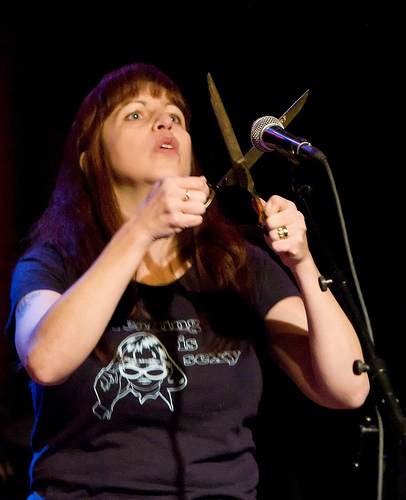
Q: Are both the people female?
A: Yes, all the people are female.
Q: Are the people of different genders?
A: No, all the people are female.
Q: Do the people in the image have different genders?
A: No, all the people are female.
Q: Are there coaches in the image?
A: No, there are no coaches.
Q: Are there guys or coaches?
A: No, there are no coaches or guys.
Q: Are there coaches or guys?
A: No, there are no coaches or guys.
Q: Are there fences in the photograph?
A: No, there are no fences.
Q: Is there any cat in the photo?
A: No, there are no cats.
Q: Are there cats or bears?
A: No, there are no cats or bears.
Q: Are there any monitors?
A: No, there are no monitors.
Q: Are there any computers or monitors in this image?
A: No, there are no monitors or computers.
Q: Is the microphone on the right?
A: Yes, the microphone is on the right of the image.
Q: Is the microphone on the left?
A: No, the microphone is on the right of the image.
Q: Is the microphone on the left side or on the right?
A: The microphone is on the right of the image.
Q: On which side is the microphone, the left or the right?
A: The microphone is on the right of the image.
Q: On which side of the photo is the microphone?
A: The microphone is on the right of the image.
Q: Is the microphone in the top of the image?
A: Yes, the microphone is in the top of the image.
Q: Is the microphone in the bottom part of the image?
A: No, the microphone is in the top of the image.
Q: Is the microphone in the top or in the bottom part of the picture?
A: The microphone is in the top of the image.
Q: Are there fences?
A: No, there are no fences.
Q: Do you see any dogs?
A: No, there are no dogs.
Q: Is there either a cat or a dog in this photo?
A: No, there are no dogs or cats.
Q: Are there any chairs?
A: No, there are no chairs.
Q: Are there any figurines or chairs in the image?
A: No, there are no chairs or figurines.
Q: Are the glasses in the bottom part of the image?
A: Yes, the glasses are in the bottom of the image.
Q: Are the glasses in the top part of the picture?
A: No, the glasses are in the bottom of the image.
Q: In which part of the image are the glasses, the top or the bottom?
A: The glasses are in the bottom of the image.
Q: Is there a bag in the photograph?
A: No, there are no bags.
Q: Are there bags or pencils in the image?
A: No, there are no bags or pencils.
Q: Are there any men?
A: No, there are no men.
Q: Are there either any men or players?
A: No, there are no men or players.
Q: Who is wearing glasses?
A: The girl is wearing glasses.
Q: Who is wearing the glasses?
A: The girl is wearing glasses.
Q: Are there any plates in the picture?
A: No, there are no plates.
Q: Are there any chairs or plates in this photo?
A: No, there are no plates or chairs.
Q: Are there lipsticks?
A: No, there are no lipsticks.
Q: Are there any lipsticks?
A: No, there are no lipsticks.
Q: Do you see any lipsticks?
A: No, there are no lipsticks.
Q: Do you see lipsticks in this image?
A: No, there are no lipsticks.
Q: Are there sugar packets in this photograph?
A: No, there are no sugar packets.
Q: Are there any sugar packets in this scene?
A: No, there are no sugar packets.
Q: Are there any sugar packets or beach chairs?
A: No, there are no sugar packets or beach chairs.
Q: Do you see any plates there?
A: No, there are no plates.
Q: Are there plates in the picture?
A: No, there are no plates.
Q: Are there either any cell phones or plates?
A: No, there are no plates or cell phones.